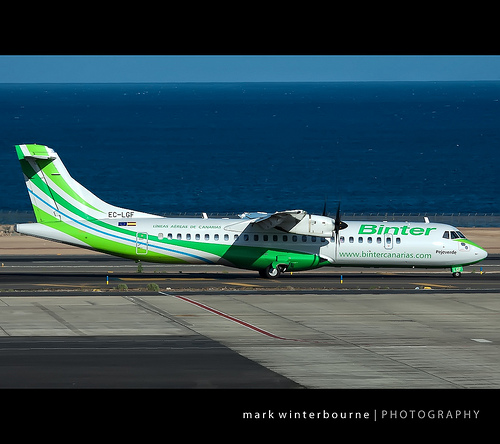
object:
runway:
[5, 257, 477, 295]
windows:
[152, 223, 403, 251]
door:
[132, 228, 152, 257]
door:
[381, 227, 393, 252]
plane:
[0, 110, 482, 272]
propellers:
[315, 195, 345, 240]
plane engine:
[319, 210, 352, 237]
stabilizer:
[17, 151, 57, 165]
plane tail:
[0, 142, 165, 222]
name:
[353, 214, 441, 239]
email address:
[333, 248, 436, 262]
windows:
[434, 224, 464, 239]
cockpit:
[432, 222, 484, 261]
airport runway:
[468, 261, 499, 279]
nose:
[467, 239, 484, 269]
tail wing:
[4, 136, 170, 222]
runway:
[2, 296, 482, 399]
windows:
[148, 229, 406, 245]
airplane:
[3, 143, 488, 278]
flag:
[113, 217, 137, 229]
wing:
[239, 201, 307, 237]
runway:
[2, 296, 484, 358]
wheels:
[257, 266, 284, 277]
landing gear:
[444, 265, 473, 280]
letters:
[354, 220, 439, 240]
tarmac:
[2, 260, 482, 335]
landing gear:
[263, 264, 282, 278]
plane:
[0, 131, 480, 279]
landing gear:
[447, 269, 467, 278]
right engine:
[298, 206, 348, 238]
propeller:
[331, 193, 345, 243]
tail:
[14, 133, 137, 216]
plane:
[8, 135, 487, 287]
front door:
[383, 227, 393, 250]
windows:
[368, 232, 402, 248]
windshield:
[449, 230, 463, 241]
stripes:
[24, 145, 321, 277]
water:
[1, 81, 498, 234]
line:
[160, 287, 284, 338]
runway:
[5, 292, 499, 386]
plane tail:
[14, 140, 159, 221]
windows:
[2, 139, 491, 287]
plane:
[157, 229, 406, 245]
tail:
[10, 137, 160, 218]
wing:
[248, 209, 312, 236]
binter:
[358, 223, 437, 235]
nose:
[456, 232, 487, 273]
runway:
[0, 254, 497, 370]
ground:
[6, 227, 493, 393]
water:
[7, 82, 499, 219]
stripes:
[5, 131, 319, 273]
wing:
[248, 203, 309, 231]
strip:
[9, 258, 499, 297]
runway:
[7, 254, 499, 383]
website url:
[335, 247, 435, 264]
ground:
[7, 292, 500, 388]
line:
[177, 290, 281, 340]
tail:
[9, 135, 169, 220]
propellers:
[314, 197, 345, 259]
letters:
[101, 209, 117, 222]